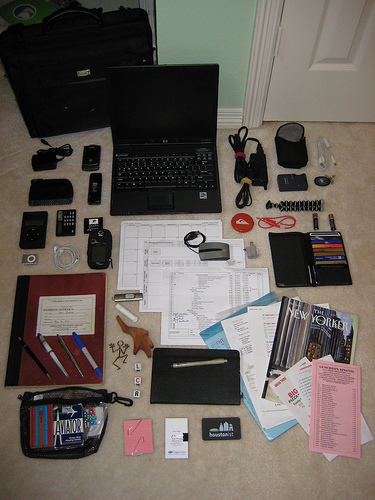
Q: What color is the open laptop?
A: Black.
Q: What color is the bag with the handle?
A: Black.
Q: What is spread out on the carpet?
A: Various items.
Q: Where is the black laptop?
A: Near the wall.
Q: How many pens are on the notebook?
A: Four.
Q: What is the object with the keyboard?
A: Laptop.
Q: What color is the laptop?
A: Black.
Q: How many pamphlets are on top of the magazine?
A: Three.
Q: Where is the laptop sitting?
A: The floor.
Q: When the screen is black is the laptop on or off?
A: Off.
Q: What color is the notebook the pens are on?
A: Red.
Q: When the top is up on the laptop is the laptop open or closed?
A: Open.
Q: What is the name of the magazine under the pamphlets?
A: The New Yorker.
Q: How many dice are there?
A: 3.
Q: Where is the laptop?
A: Top middle.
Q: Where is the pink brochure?
A: On the magazine.